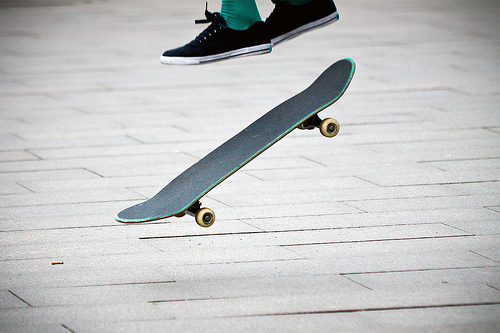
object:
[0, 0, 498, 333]
floor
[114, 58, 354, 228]
skateboard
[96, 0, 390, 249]
air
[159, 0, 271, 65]
feet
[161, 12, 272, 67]
shoes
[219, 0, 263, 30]
socks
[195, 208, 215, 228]
wheel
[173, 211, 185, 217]
wheel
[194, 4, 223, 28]
laces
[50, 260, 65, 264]
butt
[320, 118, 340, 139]
wheel